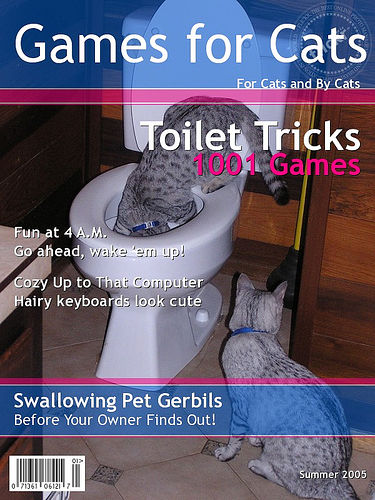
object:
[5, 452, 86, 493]
upc symbol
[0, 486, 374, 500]
bottom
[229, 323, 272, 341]
collar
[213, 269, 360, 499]
cat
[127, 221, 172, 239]
head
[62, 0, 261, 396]
toilet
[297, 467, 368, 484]
date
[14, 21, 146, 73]
game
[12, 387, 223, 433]
tagline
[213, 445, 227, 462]
left paw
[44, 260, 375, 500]
floor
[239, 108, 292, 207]
tail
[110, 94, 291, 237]
cat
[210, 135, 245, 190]
back legs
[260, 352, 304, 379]
spots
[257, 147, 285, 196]
stripes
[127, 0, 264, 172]
lid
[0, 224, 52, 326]
countertop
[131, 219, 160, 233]
collar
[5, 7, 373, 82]
title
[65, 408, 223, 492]
tile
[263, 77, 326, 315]
plunger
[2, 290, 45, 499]
vanity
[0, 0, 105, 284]
wall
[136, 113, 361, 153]
toilet tricks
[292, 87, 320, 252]
handle